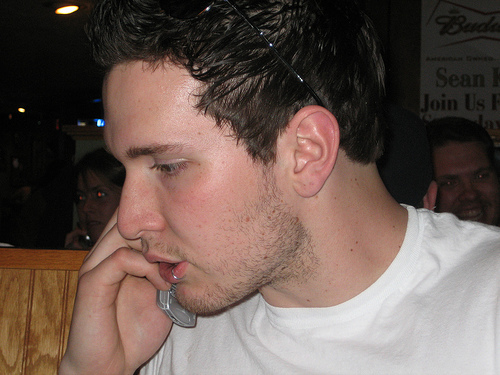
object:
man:
[53, 0, 499, 375]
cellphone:
[153, 287, 200, 329]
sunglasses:
[219, 2, 329, 109]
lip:
[170, 265, 189, 280]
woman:
[60, 154, 134, 255]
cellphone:
[77, 221, 95, 247]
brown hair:
[69, 140, 132, 197]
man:
[426, 114, 500, 230]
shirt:
[124, 200, 498, 374]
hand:
[61, 208, 182, 374]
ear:
[284, 103, 344, 200]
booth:
[3, 249, 105, 373]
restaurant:
[1, 0, 497, 373]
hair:
[80, 1, 393, 169]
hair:
[426, 115, 500, 171]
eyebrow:
[125, 139, 191, 158]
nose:
[115, 169, 166, 240]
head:
[97, 7, 389, 320]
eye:
[148, 156, 196, 175]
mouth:
[142, 253, 196, 287]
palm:
[111, 277, 176, 363]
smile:
[457, 205, 493, 222]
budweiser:
[423, 1, 500, 54]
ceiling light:
[52, 2, 82, 16]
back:
[311, 1, 396, 164]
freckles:
[244, 215, 252, 223]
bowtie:
[419, 1, 500, 52]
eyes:
[90, 187, 109, 200]